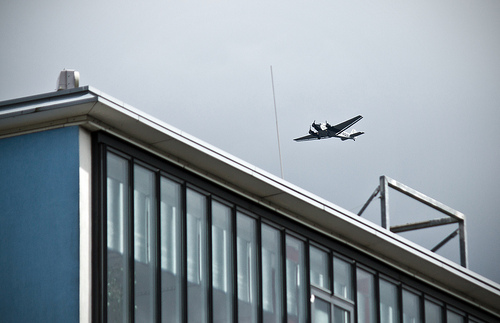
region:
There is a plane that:
[314, 117, 355, 166]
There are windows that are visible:
[146, 210, 165, 257]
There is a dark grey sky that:
[411, 38, 427, 98]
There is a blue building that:
[8, 210, 23, 247]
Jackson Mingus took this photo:
[206, 33, 346, 310]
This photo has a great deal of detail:
[161, 32, 297, 322]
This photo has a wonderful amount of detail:
[159, 39, 256, 306]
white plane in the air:
[276, 107, 376, 162]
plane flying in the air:
[293, 103, 380, 158]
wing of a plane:
[325, 115, 363, 135]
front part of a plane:
[293, 114, 335, 130]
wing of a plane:
[295, 129, 327, 143]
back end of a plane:
[338, 128, 365, 139]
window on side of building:
[102, 148, 132, 320]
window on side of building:
[135, 163, 165, 321]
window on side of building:
[160, 176, 177, 321]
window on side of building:
[190, 183, 214, 321]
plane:
[268, 92, 380, 176]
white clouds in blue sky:
[388, 43, 425, 74]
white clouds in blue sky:
[425, 103, 457, 134]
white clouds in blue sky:
[321, 153, 345, 177]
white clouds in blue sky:
[380, 2, 468, 39]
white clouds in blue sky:
[302, 53, 337, 75]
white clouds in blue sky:
[220, 48, 274, 98]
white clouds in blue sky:
[184, 22, 238, 66]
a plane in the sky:
[278, 112, 371, 151]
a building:
[120, 192, 286, 322]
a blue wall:
[16, 142, 60, 214]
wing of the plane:
[348, 111, 360, 125]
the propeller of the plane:
[304, 119, 319, 128]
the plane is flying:
[282, 104, 379, 145]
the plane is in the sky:
[296, 119, 377, 151]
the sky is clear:
[123, 20, 193, 77]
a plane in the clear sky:
[281, 114, 373, 143]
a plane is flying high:
[285, 114, 370, 151]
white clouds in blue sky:
[414, 56, 461, 100]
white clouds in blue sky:
[401, 129, 439, 166]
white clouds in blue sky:
[345, 29, 423, 67]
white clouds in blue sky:
[242, 23, 287, 77]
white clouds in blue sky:
[190, 18, 220, 49]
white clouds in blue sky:
[142, 26, 189, 54]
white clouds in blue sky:
[427, 89, 485, 120]